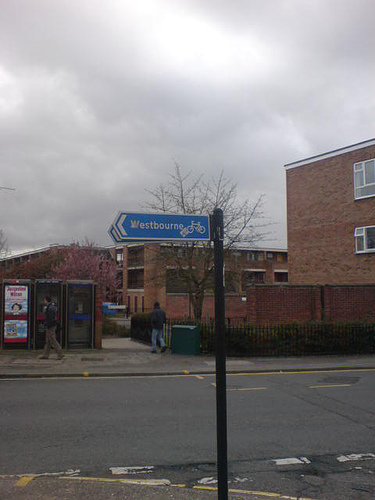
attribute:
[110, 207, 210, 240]
sign — street, blue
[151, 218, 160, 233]
letter "b" — white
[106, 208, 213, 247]
sign — blue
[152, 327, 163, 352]
jeans — blue 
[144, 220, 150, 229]
letter — white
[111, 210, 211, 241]
sign — blue, white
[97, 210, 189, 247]
sign — blue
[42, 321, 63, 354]
pants — brown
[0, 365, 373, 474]
street — gray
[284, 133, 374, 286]
building — brick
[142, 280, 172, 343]
man — walking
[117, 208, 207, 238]
street sign — blue, white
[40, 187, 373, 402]
street — city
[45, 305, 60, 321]
pocket — pant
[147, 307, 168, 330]
jacket — pocket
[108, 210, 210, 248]
street sign — blue, white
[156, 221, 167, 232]
letter — white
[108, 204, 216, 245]
sign — blue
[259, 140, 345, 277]
building — red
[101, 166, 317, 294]
sign — is blue, is white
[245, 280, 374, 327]
wall — red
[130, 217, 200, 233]
letter — white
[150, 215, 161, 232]
letter — white